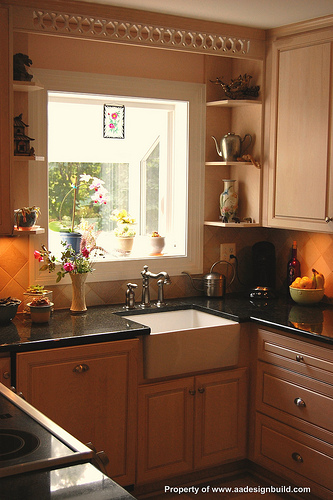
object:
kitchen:
[0, 2, 332, 498]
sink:
[122, 308, 241, 381]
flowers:
[34, 250, 45, 263]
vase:
[68, 271, 92, 312]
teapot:
[210, 133, 251, 161]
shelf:
[205, 161, 257, 168]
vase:
[219, 179, 239, 221]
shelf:
[205, 221, 255, 228]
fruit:
[299, 274, 312, 288]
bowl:
[288, 285, 322, 302]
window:
[47, 89, 187, 263]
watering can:
[181, 258, 239, 301]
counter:
[0, 307, 150, 352]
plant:
[208, 73, 262, 97]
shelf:
[205, 97, 260, 107]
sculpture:
[14, 51, 36, 81]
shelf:
[14, 82, 44, 93]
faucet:
[123, 280, 139, 308]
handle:
[128, 281, 138, 290]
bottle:
[286, 240, 300, 284]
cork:
[290, 240, 298, 248]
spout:
[210, 136, 223, 157]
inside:
[126, 309, 235, 335]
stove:
[0, 379, 93, 481]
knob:
[97, 448, 109, 464]